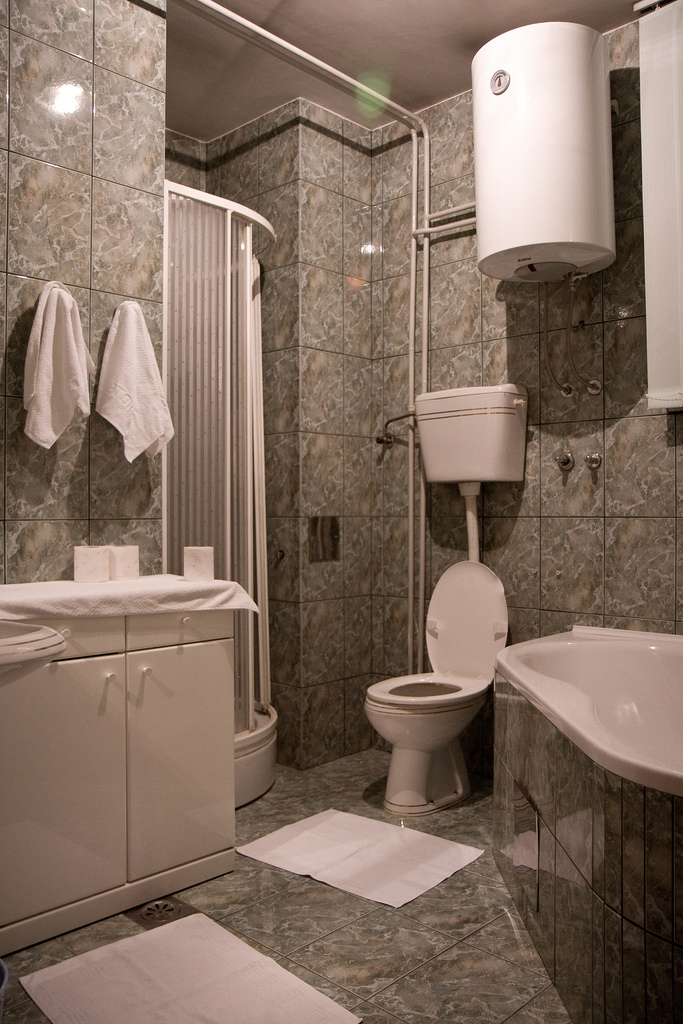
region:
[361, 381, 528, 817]
The toilet has a tank above it.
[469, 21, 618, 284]
A cylindrical water heater.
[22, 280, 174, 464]
Two white towels are hanging.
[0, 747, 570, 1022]
Two white towels are spread out on the floor.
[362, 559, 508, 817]
The lid of the toilet is open.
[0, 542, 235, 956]
Rolls of toilet paper are on the counter.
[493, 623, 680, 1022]
The inside of the tub is white.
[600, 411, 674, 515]
marble tile on the bathroom wall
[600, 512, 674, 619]
marble tile on the bathroom wall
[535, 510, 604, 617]
marble tile on the bathroom wall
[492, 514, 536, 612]
marble tile on the bathroom wall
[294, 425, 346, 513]
marble tile on the bathroom wall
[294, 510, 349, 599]
marble tile on the bathroom wall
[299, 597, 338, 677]
marble tile on the bathroom wall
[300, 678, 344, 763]
marble tile on the bathroom wall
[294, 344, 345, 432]
marble tile on the bathroom wall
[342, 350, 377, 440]
marble tile on the bathroom wall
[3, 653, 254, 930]
a pair of cabinets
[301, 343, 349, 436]
A tile in a wall.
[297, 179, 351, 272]
A tile in a wall.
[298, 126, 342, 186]
A tile in a wall.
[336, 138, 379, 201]
A tile in a wall.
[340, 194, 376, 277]
A tile in a wall.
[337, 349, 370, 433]
A tile in a wall.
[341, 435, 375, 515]
A tile in a wall.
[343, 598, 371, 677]
A tile in a wall.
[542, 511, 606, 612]
A tile in a wall.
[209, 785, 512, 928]
white towel on floor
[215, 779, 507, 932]
white towel on floor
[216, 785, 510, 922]
white towel on floor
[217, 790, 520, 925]
white towel on floor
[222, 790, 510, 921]
white towel on floor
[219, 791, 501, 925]
white towel on floor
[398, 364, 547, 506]
tank on the wall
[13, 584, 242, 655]
a pair of drawers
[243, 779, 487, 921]
rug on the floor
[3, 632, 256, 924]
a pair of cabinets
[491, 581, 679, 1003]
tub on the side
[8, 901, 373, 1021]
the rug is white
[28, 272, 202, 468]
a pair of towels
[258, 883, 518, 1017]
tile on the floor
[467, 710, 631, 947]
tile on the tub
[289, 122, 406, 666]
tile on the wall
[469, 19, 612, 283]
White wall-mounted hot water tank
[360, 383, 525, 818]
White toilet with wall-mounted tank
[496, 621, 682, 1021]
Large white bathtub with a gray surround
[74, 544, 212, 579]
Three rolls of white toilet tissue